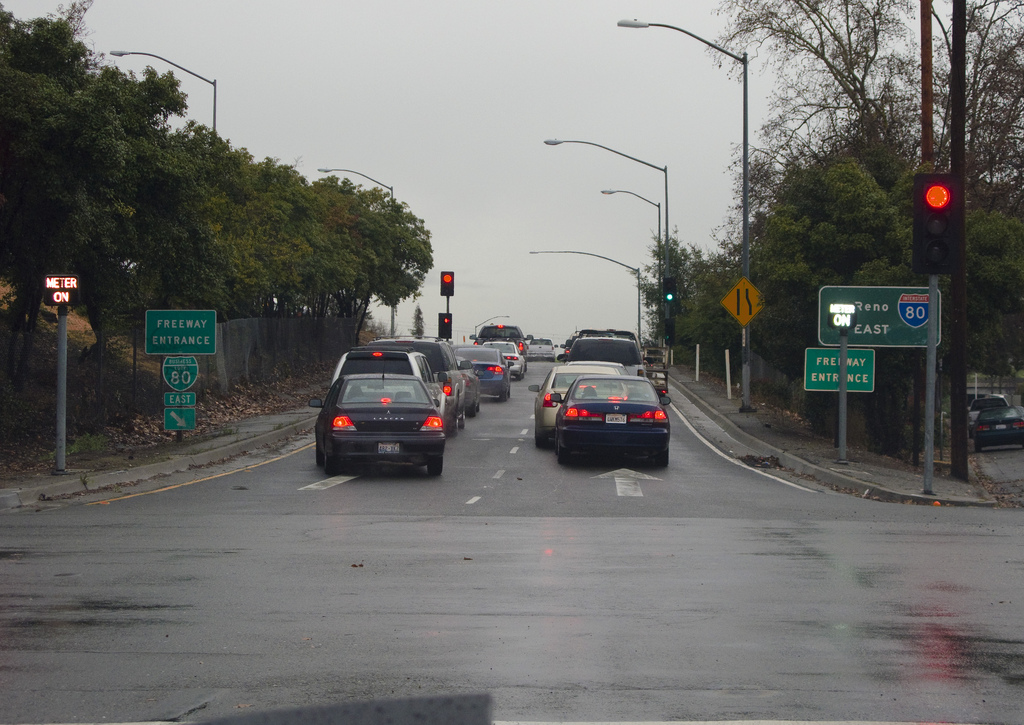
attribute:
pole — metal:
[912, 257, 947, 483]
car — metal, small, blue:
[558, 375, 669, 464]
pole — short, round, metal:
[22, 282, 153, 536]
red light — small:
[321, 406, 370, 442]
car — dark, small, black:
[310, 371, 451, 477]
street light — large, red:
[882, 176, 1010, 249]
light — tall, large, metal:
[616, 18, 762, 414]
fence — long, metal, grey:
[104, 253, 362, 472]